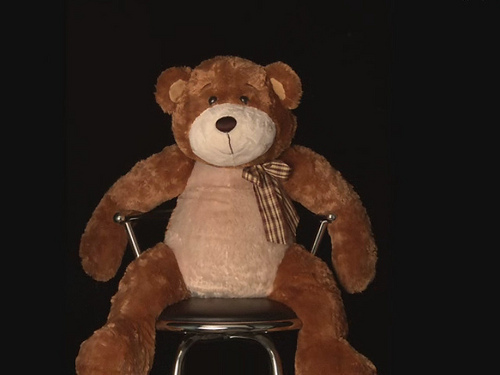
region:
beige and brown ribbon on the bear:
[239, 155, 300, 245]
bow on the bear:
[237, 143, 304, 250]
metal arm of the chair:
[302, 209, 334, 260]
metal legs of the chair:
[162, 330, 277, 373]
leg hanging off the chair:
[288, 257, 350, 373]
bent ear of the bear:
[259, 55, 314, 114]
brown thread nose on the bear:
[203, 108, 241, 135]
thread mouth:
[206, 140, 257, 155]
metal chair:
[165, 299, 297, 371]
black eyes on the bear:
[204, 88, 254, 111]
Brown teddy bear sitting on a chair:
[57, 56, 392, 371]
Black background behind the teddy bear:
[0, 0, 498, 374]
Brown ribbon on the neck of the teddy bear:
[240, 160, 303, 246]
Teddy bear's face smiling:
[152, 52, 305, 169]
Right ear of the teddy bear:
[149, 62, 197, 115]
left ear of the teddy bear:
[262, 59, 304, 111]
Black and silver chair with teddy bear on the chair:
[113, 206, 337, 373]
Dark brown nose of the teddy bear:
[212, 114, 238, 133]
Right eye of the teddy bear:
[204, 93, 220, 107]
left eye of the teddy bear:
[238, 95, 251, 106]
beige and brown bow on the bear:
[234, 156, 310, 248]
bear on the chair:
[61, 40, 355, 359]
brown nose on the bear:
[207, 109, 239, 137]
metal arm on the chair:
[111, 191, 180, 273]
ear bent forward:
[268, 48, 305, 108]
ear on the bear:
[151, 68, 191, 108]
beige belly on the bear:
[179, 165, 280, 332]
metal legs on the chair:
[159, 337, 279, 368]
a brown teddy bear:
[75, 31, 400, 373]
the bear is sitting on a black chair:
[52, 28, 469, 373]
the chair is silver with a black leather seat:
[49, 28, 402, 373]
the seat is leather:
[125, 280, 330, 352]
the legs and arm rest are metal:
[101, 203, 354, 373]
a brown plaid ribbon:
[228, 149, 315, 245]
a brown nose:
[213, 109, 254, 136]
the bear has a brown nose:
[42, 40, 396, 373]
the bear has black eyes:
[68, 21, 408, 371]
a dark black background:
[3, 0, 497, 372]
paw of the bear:
[315, 220, 372, 290]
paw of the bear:
[283, 332, 382, 373]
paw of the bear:
[55, 323, 171, 373]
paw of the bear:
[84, 243, 129, 285]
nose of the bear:
[205, 113, 251, 159]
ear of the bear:
[154, 70, 189, 110]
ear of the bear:
[260, 61, 290, 111]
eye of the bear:
[236, 92, 251, 102]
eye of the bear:
[206, 93, 226, 115]